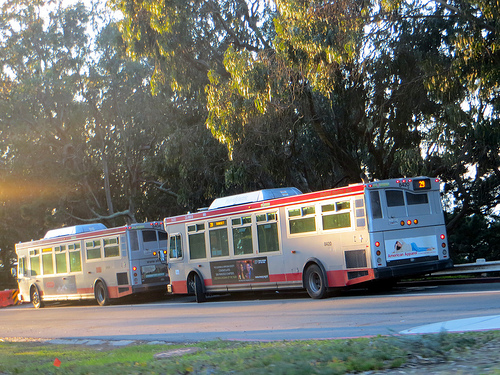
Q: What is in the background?
A: Trees.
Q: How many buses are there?
A: Two.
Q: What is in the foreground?
A: Grass.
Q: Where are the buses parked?
A: On a street.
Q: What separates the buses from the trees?
A: A guard rail.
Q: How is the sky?
A: It is clear.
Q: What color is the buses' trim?
A: Red.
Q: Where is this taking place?
A: On a highway.